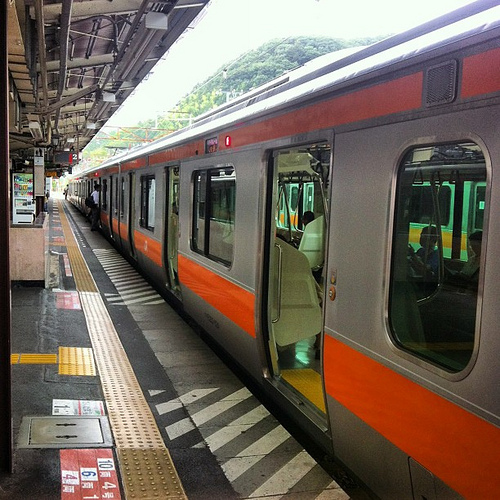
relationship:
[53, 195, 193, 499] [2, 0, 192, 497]
boarding ramp at train station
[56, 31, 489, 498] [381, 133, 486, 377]
train has window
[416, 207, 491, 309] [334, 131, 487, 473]
people in train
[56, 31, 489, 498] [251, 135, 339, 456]
train has door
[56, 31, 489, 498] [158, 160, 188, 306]
train has door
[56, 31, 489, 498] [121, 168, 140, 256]
train has door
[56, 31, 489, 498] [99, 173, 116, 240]
train has door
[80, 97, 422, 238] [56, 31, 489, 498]
man in train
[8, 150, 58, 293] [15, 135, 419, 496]
booth in train station